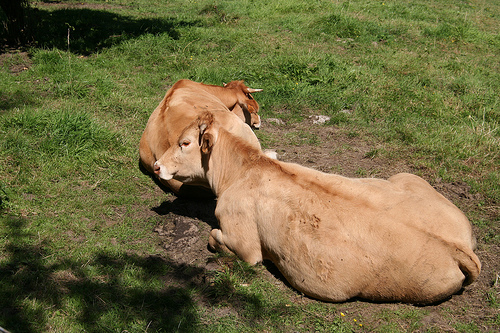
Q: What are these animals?
A: Cows.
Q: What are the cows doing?
A: Lying down.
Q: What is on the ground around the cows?
A: Green grass.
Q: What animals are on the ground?
A: Cows.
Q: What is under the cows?
A: Patch of dirt.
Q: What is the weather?
A: Sunny.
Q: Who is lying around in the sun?
A: Two cows.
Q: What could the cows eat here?
A: The grass.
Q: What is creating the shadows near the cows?
A: Trees.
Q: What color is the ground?
A: Green.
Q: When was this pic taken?
A: During the daytime.